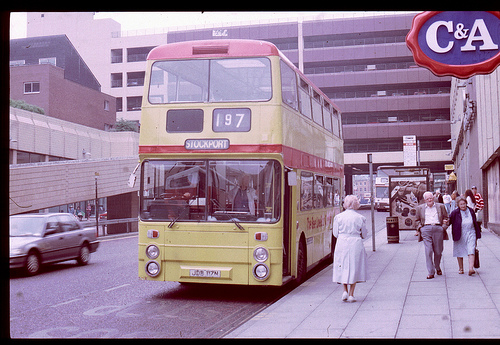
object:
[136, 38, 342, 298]
bus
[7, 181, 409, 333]
street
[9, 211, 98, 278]
car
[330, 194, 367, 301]
woman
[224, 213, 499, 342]
sidewalk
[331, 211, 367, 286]
jacket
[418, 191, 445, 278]
man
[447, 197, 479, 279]
woman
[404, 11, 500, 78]
sign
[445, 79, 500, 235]
building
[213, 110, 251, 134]
sign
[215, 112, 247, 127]
197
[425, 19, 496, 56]
letters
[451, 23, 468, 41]
& sumbol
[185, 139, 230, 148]
marquee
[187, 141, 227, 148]
stockport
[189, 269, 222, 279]
license plate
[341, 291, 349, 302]
shoe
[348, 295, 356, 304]
shoe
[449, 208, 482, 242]
jacket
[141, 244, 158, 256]
headlight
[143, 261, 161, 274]
headlight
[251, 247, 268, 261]
headlight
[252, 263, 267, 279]
headlight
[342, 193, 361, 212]
hair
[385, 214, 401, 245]
trash can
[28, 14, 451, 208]
parking deck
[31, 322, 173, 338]
stop word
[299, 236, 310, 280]
tire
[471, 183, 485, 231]
man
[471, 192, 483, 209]
shirt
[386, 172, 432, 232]
bus stop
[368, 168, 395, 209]
bus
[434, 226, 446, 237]
pockets